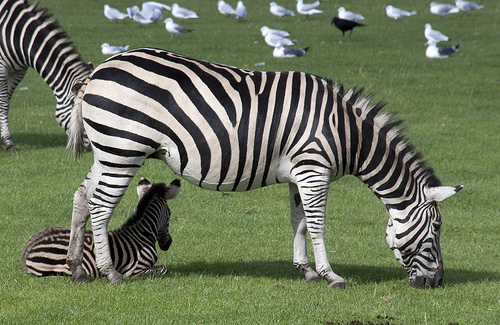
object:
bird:
[422, 23, 450, 47]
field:
[0, 0, 499, 324]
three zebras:
[0, 0, 463, 289]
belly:
[167, 120, 285, 193]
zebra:
[23, 176, 182, 280]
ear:
[424, 183, 465, 202]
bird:
[329, 16, 366, 37]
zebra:
[1, 0, 96, 153]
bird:
[423, 39, 459, 60]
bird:
[334, 6, 365, 21]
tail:
[63, 77, 91, 162]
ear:
[166, 178, 181, 201]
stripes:
[60, 47, 465, 289]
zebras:
[2, 1, 489, 316]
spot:
[284, 184, 323, 236]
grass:
[0, 0, 499, 324]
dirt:
[22, 227, 92, 279]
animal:
[67, 46, 465, 290]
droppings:
[342, 310, 392, 324]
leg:
[290, 165, 333, 273]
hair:
[349, 83, 445, 193]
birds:
[100, 41, 132, 56]